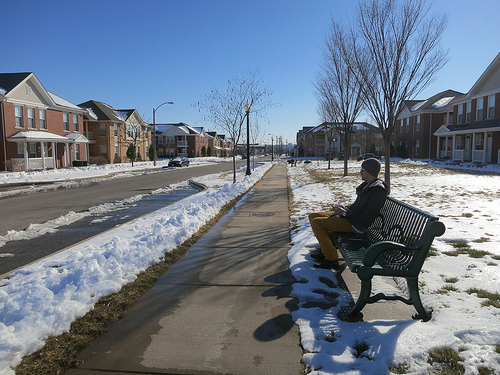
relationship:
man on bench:
[312, 156, 388, 268] [328, 185, 445, 324]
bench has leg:
[332, 195, 446, 323] [406, 277, 429, 314]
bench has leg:
[332, 195, 446, 323] [349, 274, 373, 320]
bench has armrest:
[330, 191, 452, 326] [342, 237, 436, 282]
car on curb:
[168, 156, 190, 168] [122, 155, 203, 175]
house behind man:
[294, 121, 390, 160] [312, 156, 388, 268]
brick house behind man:
[389, 88, 469, 157] [312, 156, 388, 268]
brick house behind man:
[432, 52, 500, 164] [312, 156, 388, 268]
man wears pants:
[312, 156, 388, 268] [309, 211, 356, 260]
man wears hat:
[312, 156, 388, 268] [360, 159, 380, 173]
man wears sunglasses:
[308, 157, 390, 268] [358, 167, 368, 177]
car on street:
[168, 156, 190, 168] [5, 133, 252, 241]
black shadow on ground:
[254, 253, 327, 340] [0, 155, 500, 372]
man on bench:
[308, 157, 390, 268] [328, 185, 445, 324]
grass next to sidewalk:
[1, 143, 279, 373] [69, 142, 297, 374]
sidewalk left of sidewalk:
[0, 160, 306, 371] [118, 127, 303, 361]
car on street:
[165, 153, 193, 168] [10, 143, 266, 239]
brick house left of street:
[2, 70, 89, 166] [12, 126, 271, 259]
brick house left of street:
[84, 97, 152, 159] [12, 126, 271, 259]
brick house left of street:
[151, 122, 208, 154] [12, 126, 271, 259]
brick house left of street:
[432, 52, 496, 164] [12, 126, 271, 259]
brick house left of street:
[389, 88, 469, 157] [12, 126, 271, 259]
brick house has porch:
[0, 71, 89, 170] [11, 129, 72, 176]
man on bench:
[308, 157, 390, 268] [290, 153, 472, 338]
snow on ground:
[286, 156, 498, 371] [0, 155, 500, 372]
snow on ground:
[0, 152, 274, 373] [0, 155, 500, 372]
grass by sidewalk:
[16, 184, 256, 372] [73, 159, 306, 371]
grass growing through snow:
[416, 328, 472, 373] [412, 173, 464, 193]